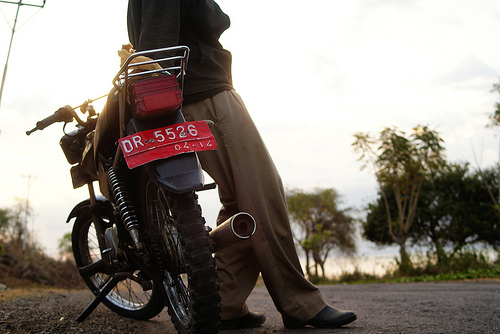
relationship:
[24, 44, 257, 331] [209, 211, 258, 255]
motorcycle has an exhast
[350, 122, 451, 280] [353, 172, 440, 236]
tree has branches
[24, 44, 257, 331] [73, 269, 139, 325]
motorcycle has kickstand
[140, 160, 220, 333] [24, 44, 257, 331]
tire in back of motorcycle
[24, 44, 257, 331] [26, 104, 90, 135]
motorcycle has handle bar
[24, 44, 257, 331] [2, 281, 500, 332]
motorcycle on top of road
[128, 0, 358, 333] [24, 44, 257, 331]
person leaning on motorcycle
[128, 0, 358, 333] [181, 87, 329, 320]
person wearing pants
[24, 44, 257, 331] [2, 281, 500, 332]
motorcycle on black road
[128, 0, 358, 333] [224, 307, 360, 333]
person wearing black shoes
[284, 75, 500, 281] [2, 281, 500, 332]
trees near road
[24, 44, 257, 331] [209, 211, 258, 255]
motorcycle has a exhast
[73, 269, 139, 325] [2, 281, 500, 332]
kickstand on top of road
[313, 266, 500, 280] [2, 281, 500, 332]
grass near road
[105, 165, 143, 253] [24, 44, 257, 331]
shocks on motorcycle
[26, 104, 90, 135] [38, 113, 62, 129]
handle bar has a brake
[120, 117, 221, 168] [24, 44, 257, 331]
license plate on motorcycle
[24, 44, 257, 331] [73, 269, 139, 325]
motorcycle has a kickstand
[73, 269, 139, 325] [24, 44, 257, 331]
kickstand holding motorcycle